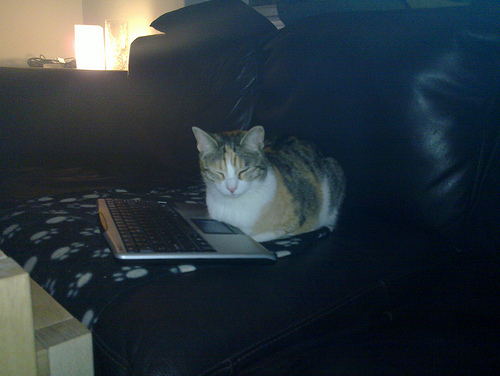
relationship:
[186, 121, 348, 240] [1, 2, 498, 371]
cat laying on couch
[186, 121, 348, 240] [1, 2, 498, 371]
cat sleeping on couch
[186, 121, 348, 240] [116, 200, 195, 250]
cat near keyboard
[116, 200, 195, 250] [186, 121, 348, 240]
keyboard near cat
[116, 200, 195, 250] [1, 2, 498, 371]
keyboard across couch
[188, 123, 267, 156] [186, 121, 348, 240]
ears of cat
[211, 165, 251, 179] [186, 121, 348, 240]
eyes of cat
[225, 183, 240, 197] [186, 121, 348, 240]
nose of cat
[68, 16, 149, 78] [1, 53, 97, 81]
light on table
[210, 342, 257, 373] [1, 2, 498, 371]
stitching in couch